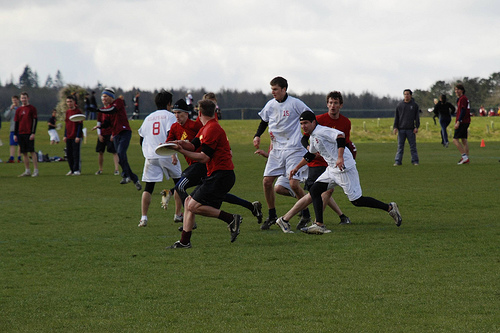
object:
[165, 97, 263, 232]
people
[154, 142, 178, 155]
frisbee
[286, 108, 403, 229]
man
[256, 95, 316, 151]
shirt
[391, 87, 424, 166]
man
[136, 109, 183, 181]
uniform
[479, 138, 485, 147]
cone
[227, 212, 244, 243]
shoe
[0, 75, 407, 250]
group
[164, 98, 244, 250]
person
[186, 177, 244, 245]
leg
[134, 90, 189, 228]
person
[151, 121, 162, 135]
number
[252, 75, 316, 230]
boy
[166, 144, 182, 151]
hand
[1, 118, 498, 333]
ground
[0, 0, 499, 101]
sky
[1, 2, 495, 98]
cloud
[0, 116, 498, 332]
grass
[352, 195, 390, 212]
socks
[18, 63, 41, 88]
tree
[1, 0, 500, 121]
background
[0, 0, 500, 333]
air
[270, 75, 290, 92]
hair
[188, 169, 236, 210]
shorts